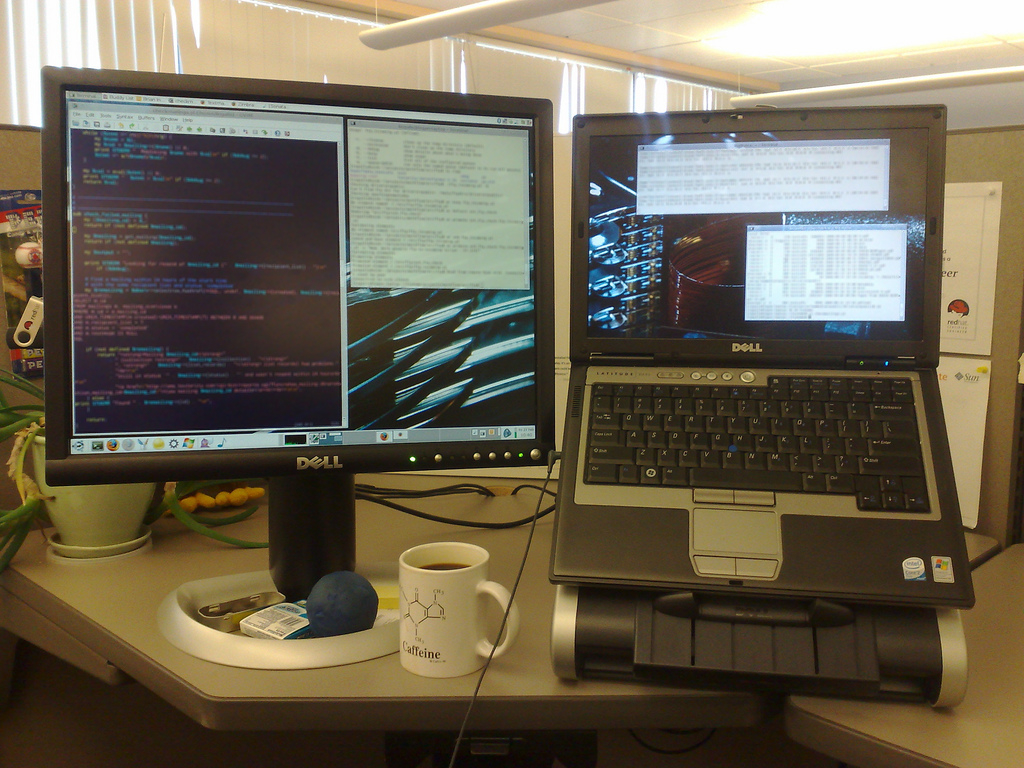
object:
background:
[5, 4, 988, 298]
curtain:
[0, 0, 637, 138]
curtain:
[636, 74, 753, 114]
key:
[683, 415, 704, 433]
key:
[754, 434, 780, 454]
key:
[748, 417, 770, 435]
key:
[801, 401, 826, 421]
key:
[776, 435, 802, 455]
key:
[768, 451, 792, 473]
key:
[721, 452, 746, 471]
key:
[635, 446, 658, 468]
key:
[688, 430, 713, 451]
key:
[788, 452, 815, 472]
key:
[694, 398, 717, 417]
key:
[632, 396, 655, 416]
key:
[716, 398, 738, 417]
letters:
[731, 342, 740, 352]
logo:
[292, 454, 349, 473]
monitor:
[39, 64, 560, 676]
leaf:
[169, 496, 261, 527]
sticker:
[930, 555, 957, 586]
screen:
[61, 79, 541, 462]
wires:
[510, 483, 557, 498]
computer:
[32, 52, 988, 703]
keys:
[586, 461, 621, 485]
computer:
[546, 102, 981, 614]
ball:
[302, 562, 383, 638]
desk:
[0, 466, 1024, 767]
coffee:
[406, 549, 471, 567]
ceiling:
[257, 0, 1024, 132]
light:
[684, 0, 993, 63]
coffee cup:
[395, 538, 528, 686]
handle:
[477, 573, 520, 658]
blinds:
[147, 0, 179, 76]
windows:
[0, 0, 754, 135]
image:
[65, 84, 536, 462]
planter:
[16, 409, 167, 556]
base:
[45, 523, 153, 564]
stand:
[548, 582, 977, 710]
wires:
[354, 492, 555, 531]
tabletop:
[0, 461, 1022, 766]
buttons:
[903, 492, 931, 513]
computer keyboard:
[589, 370, 932, 556]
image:
[585, 130, 928, 341]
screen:
[584, 124, 937, 346]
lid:
[562, 99, 951, 367]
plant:
[0, 362, 273, 577]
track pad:
[684, 497, 790, 569]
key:
[619, 412, 643, 431]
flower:
[0, 360, 264, 576]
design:
[402, 577, 463, 660]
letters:
[294, 455, 310, 472]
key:
[744, 451, 768, 471]